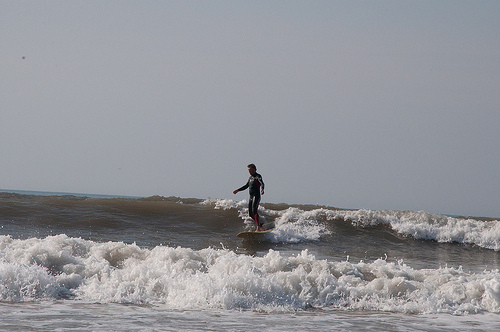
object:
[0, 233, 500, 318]
wave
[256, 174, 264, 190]
arm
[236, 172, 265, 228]
wetsuit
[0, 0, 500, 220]
sky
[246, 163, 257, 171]
black hair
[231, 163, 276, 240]
man surfing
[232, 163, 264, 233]
man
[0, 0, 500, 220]
cloud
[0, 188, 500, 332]
water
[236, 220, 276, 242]
surfboard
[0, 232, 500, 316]
foam